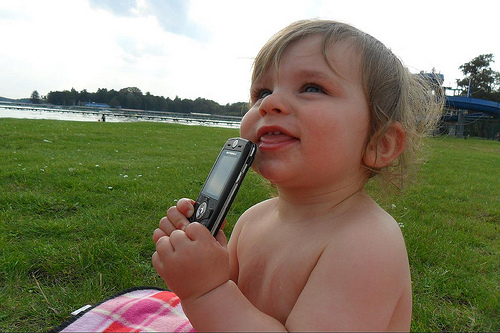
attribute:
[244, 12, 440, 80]
hair — brown, curly, short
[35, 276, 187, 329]
blanket — pink, plaid, checkered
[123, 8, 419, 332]
child — sitting, smiling, shirtless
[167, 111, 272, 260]
phone — black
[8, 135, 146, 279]
grass — green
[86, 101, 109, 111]
roof — blue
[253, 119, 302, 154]
mouth — open, out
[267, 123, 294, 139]
teeth — small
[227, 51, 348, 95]
eyes — blue